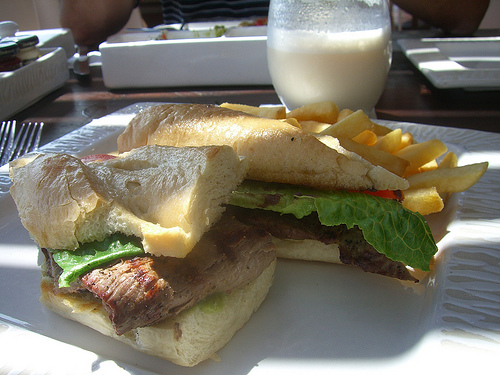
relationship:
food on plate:
[7, 101, 489, 367] [25, 77, 442, 334]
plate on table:
[25, 77, 442, 334] [31, 18, 428, 322]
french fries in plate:
[221, 101, 488, 214] [0, 102, 500, 375]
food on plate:
[7, 101, 489, 367] [0, 102, 500, 375]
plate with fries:
[0, 102, 500, 375] [217, 102, 488, 217]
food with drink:
[7, 101, 489, 367] [262, 3, 389, 115]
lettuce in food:
[45, 220, 150, 287] [7, 101, 489, 367]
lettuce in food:
[225, 156, 438, 274] [7, 101, 489, 367]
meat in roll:
[39, 215, 277, 337] [10, 147, 254, 202]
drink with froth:
[269, 28, 394, 119] [261, 26, 391, 50]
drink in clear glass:
[269, 28, 394, 119] [265, 0, 389, 121]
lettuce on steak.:
[45, 233, 149, 285] [51, 227, 270, 332]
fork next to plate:
[0, 120, 42, 165] [283, 284, 422, 371]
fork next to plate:
[2, 119, 17, 154] [283, 284, 422, 371]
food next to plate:
[25, 145, 281, 372] [283, 284, 422, 371]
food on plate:
[7, 101, 489, 367] [303, 249, 483, 348]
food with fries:
[7, 101, 489, 367] [217, 102, 488, 217]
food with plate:
[7, 101, 489, 367] [288, 273, 482, 358]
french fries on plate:
[221, 101, 488, 214] [0, 102, 500, 375]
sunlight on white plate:
[312, 334, 469, 374] [2, 190, 383, 373]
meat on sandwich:
[81, 215, 440, 313] [17, 67, 496, 334]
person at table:
[57, 1, 488, 51] [0, 29, 497, 159]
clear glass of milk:
[260, 1, 399, 101] [272, 23, 386, 104]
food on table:
[7, 101, 489, 367] [4, 33, 461, 373]